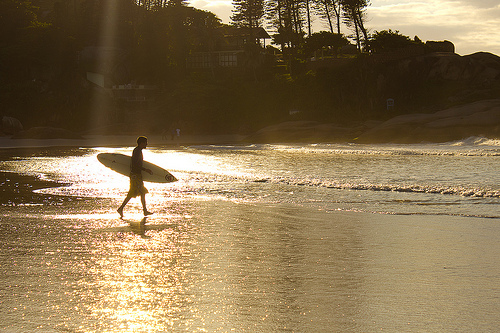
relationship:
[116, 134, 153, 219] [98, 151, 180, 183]
surfer carrying a surfboard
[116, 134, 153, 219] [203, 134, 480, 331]
surfer walking to ocean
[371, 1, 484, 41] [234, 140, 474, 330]
sky over ocean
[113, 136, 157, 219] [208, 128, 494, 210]
person walking towards water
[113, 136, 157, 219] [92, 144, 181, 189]
person has surfboard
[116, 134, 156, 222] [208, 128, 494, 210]
surfer walking towards water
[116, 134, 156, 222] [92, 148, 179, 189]
surfer has surfboard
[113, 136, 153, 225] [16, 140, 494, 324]
person walking on beach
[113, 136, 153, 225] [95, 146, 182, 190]
person has surfboard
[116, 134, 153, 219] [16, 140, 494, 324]
surfer on beach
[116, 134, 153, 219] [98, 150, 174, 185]
surfer has surfboard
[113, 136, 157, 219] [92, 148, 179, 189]
person carry surfboard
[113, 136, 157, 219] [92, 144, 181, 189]
person carry surfboard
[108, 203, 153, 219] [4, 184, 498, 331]
feet on beach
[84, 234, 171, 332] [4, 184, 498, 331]
sunlight on beach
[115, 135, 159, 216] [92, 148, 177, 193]
man holds surfboard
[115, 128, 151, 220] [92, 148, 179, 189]
man carry surfboard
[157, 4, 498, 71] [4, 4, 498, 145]
house on hill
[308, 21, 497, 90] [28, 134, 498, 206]
outcropping near beach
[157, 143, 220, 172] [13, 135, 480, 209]
sun on water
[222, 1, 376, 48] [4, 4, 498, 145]
trees on hill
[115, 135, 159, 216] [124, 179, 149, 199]
man wears shorts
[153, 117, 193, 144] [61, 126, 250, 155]
people in beach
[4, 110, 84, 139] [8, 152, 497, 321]
rocks on beach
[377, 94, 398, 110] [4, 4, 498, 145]
sign on hill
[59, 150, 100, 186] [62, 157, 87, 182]
ray of sunshine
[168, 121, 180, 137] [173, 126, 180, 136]
person wears shirt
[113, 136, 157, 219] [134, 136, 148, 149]
person has head